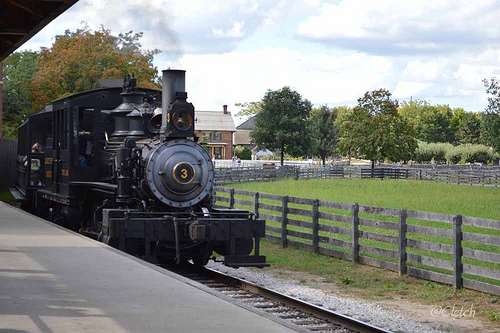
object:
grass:
[405, 181, 500, 219]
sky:
[13, 0, 499, 111]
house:
[193, 111, 234, 160]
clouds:
[9, 0, 498, 111]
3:
[181, 169, 188, 179]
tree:
[251, 86, 314, 165]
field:
[214, 180, 500, 309]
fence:
[215, 188, 499, 297]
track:
[197, 266, 384, 332]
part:
[242, 299, 268, 302]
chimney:
[223, 105, 227, 114]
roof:
[194, 111, 236, 130]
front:
[145, 139, 213, 210]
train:
[0, 70, 267, 273]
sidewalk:
[0, 203, 299, 333]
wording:
[431, 303, 476, 317]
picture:
[0, 0, 499, 333]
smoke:
[103, 1, 181, 62]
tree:
[337, 88, 418, 167]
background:
[0, 0, 499, 182]